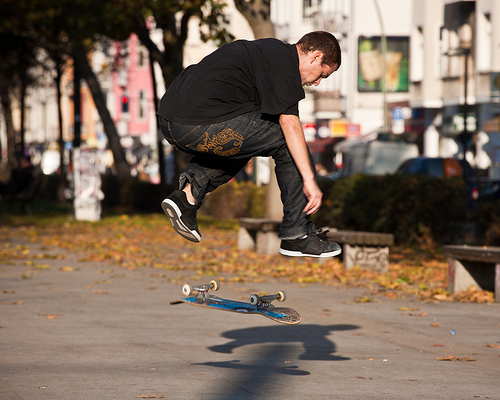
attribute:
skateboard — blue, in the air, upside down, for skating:
[164, 273, 305, 327]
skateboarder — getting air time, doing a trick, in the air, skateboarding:
[143, 24, 365, 261]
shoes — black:
[160, 183, 348, 266]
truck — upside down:
[177, 279, 222, 301]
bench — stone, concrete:
[232, 213, 281, 260]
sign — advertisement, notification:
[352, 34, 417, 99]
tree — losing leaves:
[3, 1, 156, 200]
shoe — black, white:
[159, 188, 206, 245]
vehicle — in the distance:
[330, 136, 421, 183]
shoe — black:
[276, 220, 346, 262]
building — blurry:
[405, 0, 499, 184]